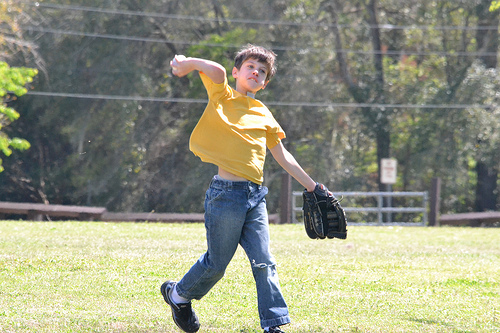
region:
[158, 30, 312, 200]
child wearing yellow t-shirt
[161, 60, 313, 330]
boy wearing blue jeans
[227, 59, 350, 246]
boy with baseball mitt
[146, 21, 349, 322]
boy with baseball in hand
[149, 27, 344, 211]
boy throwing ball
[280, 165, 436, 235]
metal road gate with wood posts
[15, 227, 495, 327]
field with green grass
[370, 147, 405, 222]
street sign on pole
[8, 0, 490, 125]
overhead power lines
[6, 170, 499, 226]
fence made of wood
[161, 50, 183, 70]
white baseball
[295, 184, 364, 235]
black baseball glove in boy's hand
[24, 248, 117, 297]
green grass on the field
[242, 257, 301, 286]
torn leg on blue jeans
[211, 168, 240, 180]
boy's white skin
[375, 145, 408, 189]
white sign on tree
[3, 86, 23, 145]
leaves of bright green tree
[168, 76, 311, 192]
yellow tee shirt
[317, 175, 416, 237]
large silver fence in the back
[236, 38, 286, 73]
boy's short black hair cut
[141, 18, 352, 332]
The boy is wearing a baseball glove.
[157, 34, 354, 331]
The baseball glove is black.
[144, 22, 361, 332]
The baseball glove is leather.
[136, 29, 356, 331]
The boy is wearing a shirt.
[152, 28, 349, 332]
The boy's shirt has sleeve.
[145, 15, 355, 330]
The boy's shirt has short sleeves.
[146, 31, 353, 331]
The boy is wearing blue jeans.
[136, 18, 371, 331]
The boy is standing.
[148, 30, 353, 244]
The boy has hair.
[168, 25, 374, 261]
The boy has short hair.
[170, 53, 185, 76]
White baseball in the boy's hand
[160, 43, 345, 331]
A boy pitching the baseball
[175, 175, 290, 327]
Blue jeans the boy is wearing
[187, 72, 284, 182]
Yellow tshirt the boy is wearing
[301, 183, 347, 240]
Black baseball gloves the boy is wearing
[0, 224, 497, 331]
Ground covered with grass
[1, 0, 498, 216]
Big green trees in the background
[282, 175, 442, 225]
metal railing at the edge of the field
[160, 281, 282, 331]
Black sports shoes the boy is wearing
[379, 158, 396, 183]
A white sign board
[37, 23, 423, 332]
boy throwing baseball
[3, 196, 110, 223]
bench is made of wood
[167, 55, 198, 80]
baseball in boy's hand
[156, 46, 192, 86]
baseball is white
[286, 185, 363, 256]
boy wearing baseball glove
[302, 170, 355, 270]
baseball glove is black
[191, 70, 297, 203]
boy wearing yellow shirt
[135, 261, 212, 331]
boy wearing black and white sneakers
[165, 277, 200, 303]
boy wearing white socks